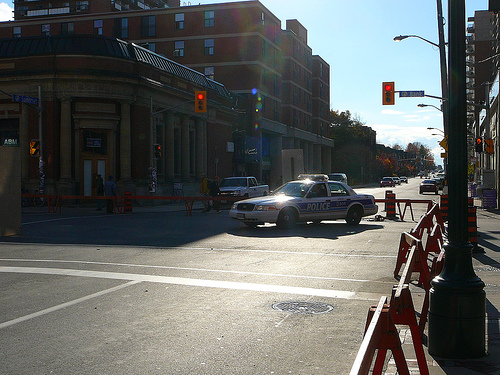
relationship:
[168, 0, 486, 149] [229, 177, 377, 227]
sky above car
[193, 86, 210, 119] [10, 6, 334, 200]
light near building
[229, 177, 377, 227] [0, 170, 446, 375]
car on road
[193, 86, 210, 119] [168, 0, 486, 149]
light under sky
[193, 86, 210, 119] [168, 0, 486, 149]
light below sky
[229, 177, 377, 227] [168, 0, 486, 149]
car below sky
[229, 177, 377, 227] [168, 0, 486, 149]
car under sky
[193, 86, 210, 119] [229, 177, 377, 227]
light above car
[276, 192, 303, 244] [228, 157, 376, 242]
tire of car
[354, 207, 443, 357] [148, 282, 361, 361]
barricade on road